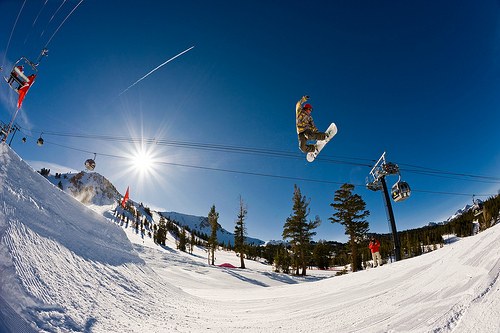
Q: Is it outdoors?
A: Yes, it is outdoors.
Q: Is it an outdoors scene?
A: Yes, it is outdoors.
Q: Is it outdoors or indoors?
A: It is outdoors.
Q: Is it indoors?
A: No, it is outdoors.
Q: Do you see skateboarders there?
A: Yes, there is a skateboarder.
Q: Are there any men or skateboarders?
A: Yes, there is a skateboarder.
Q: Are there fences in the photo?
A: No, there are no fences.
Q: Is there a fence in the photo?
A: No, there are no fences.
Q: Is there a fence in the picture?
A: No, there are no fences.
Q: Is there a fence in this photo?
A: No, there are no fences.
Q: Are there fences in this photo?
A: No, there are no fences.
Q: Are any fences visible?
A: No, there are no fences.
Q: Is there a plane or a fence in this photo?
A: No, there are no fences or airplanes.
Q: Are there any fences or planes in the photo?
A: No, there are no fences or planes.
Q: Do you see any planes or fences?
A: No, there are no fences or planes.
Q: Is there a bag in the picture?
A: No, there are no bags.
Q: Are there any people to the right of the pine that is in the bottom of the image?
A: Yes, there is a person to the right of the pine.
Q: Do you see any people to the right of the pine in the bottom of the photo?
A: Yes, there is a person to the right of the pine.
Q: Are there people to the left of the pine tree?
A: No, the person is to the right of the pine tree.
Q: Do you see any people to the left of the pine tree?
A: No, the person is to the right of the pine tree.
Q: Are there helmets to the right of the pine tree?
A: No, there is a person to the right of the pine tree.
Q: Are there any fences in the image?
A: No, there are no fences.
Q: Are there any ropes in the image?
A: No, there are no ropes.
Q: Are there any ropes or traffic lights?
A: No, there are no ropes or traffic lights.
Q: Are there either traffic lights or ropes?
A: No, there are no ropes or traffic lights.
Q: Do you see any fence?
A: No, there are no fences.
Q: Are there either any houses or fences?
A: No, there are no fences or houses.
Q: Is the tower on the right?
A: Yes, the tower is on the right of the image.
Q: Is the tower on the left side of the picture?
A: No, the tower is on the right of the image.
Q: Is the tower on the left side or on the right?
A: The tower is on the right of the image.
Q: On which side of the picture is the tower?
A: The tower is on the right of the image.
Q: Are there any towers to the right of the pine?
A: Yes, there is a tower to the right of the pine.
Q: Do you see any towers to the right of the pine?
A: Yes, there is a tower to the right of the pine.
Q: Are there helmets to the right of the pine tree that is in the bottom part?
A: No, there is a tower to the right of the pine tree.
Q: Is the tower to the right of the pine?
A: Yes, the tower is to the right of the pine.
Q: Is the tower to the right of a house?
A: No, the tower is to the right of the pine.